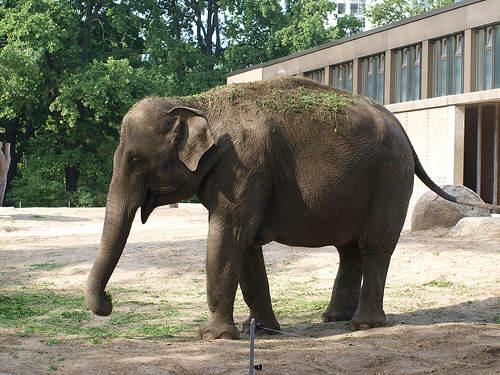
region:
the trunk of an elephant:
[85, 172, 144, 317]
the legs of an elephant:
[194, 205, 398, 336]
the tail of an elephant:
[414, 160, 499, 219]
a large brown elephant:
[83, 75, 499, 337]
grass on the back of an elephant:
[205, 91, 355, 134]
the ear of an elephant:
[160, 105, 219, 170]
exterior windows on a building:
[432, 27, 499, 96]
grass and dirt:
[0, 209, 85, 374]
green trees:
[0, 1, 105, 205]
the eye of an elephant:
[128, 152, 143, 169]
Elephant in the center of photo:
[82, 80, 446, 340]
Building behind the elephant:
[207, 1, 496, 218]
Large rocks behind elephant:
[406, 171, 498, 258]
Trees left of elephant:
[2, 0, 239, 212]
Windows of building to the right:
[321, 10, 496, 106]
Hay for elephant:
[0, 255, 290, 361]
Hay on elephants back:
[150, 55, 420, 132]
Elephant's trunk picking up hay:
[43, 250, 158, 341]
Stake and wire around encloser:
[0, 308, 495, 371]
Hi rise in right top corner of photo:
[305, 0, 412, 48]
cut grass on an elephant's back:
[174, 73, 359, 127]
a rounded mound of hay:
[413, 179, 489, 233]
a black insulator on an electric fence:
[253, 320, 263, 333]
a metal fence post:
[244, 313, 264, 373]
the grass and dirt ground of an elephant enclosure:
[2, 208, 498, 368]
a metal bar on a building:
[469, 101, 486, 206]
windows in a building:
[426, 29, 472, 96]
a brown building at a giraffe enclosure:
[217, 1, 498, 220]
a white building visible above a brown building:
[323, 0, 386, 40]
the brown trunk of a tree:
[58, 155, 80, 208]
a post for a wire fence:
[240, 309, 266, 374]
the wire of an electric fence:
[265, 323, 493, 373]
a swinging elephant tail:
[400, 121, 497, 221]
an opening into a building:
[450, 98, 498, 219]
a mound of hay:
[414, 181, 498, 222]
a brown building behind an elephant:
[211, 1, 496, 231]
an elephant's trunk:
[81, 195, 147, 327]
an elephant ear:
[165, 100, 215, 165]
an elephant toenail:
[201, 330, 214, 341]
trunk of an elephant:
[77, 197, 144, 332]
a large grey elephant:
[98, 85, 442, 340]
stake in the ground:
[238, 318, 269, 373]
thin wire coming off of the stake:
[258, 319, 485, 368]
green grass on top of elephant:
[194, 86, 352, 139]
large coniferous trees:
[41, 62, 130, 156]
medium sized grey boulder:
[412, 185, 484, 235]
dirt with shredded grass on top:
[9, 229, 73, 347]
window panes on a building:
[393, 18, 492, 102]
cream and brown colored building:
[371, 7, 483, 229]